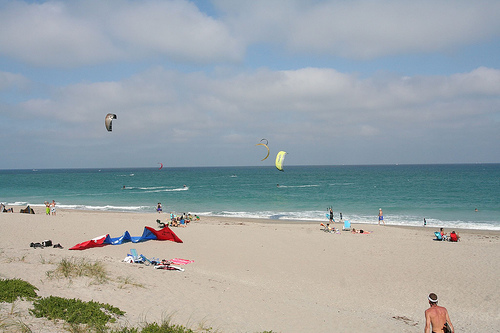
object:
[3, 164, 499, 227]
water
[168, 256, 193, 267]
towel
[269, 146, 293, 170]
kite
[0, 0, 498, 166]
clouds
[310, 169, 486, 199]
sea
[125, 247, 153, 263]
chair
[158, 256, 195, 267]
chair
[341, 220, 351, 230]
chair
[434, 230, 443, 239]
chair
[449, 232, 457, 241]
chair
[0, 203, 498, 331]
sand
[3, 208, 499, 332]
floor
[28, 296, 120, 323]
green plants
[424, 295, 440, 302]
band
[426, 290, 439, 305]
head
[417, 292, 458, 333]
man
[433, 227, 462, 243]
people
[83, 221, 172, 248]
tents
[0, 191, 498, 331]
beach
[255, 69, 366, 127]
puffy clouds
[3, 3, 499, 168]
sky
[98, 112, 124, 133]
wind kites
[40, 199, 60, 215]
two people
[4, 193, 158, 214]
waves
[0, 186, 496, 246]
shore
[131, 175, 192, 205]
waves